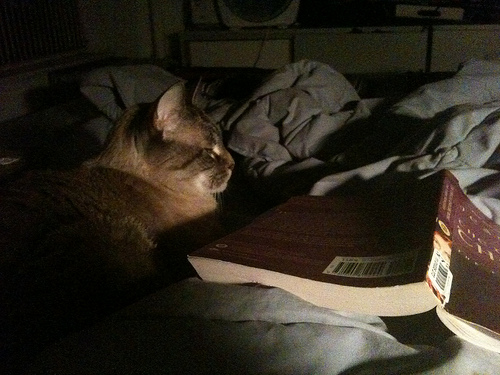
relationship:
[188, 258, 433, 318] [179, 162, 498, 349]
paper in book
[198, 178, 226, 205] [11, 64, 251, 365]
whiskers on cat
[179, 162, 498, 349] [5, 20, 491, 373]
book on bed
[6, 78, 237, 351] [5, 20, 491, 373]
cat laying on bed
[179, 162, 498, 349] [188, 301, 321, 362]
book on cover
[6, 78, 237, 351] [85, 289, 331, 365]
cat lying on cover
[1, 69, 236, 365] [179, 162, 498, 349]
cat next to book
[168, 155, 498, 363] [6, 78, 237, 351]
book next to cat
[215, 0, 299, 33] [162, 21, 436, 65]
fan on shelf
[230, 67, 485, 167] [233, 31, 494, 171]
cover bunched on blanket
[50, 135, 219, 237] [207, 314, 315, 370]
cat on bed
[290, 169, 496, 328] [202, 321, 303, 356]
book on bed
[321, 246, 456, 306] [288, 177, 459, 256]
barcode on book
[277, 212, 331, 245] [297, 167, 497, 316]
lettering on book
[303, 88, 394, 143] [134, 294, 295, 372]
blanket on bed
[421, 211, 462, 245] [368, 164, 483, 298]
sticker on book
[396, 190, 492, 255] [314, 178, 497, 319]
lettering on book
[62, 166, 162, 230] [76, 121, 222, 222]
stripes on cat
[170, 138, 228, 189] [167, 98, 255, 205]
stripe on face